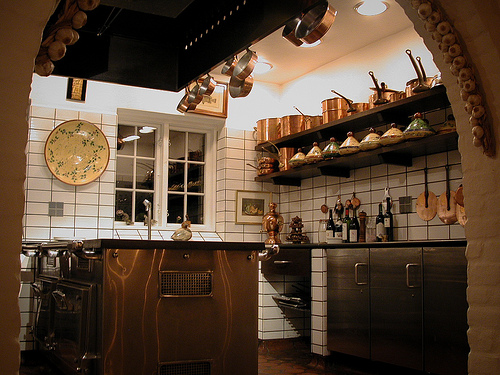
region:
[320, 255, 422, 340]
silver handles on cupboards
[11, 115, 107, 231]
decorative plate hanging on wall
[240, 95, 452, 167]
cooking pots and serving bowls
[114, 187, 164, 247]
a tall silver sink faucet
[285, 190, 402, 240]
bottles of wine on the counter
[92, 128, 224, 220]
a window with reflection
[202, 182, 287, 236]
a oicture hanging on wall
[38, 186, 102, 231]
white and gray tile back splash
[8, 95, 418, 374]
a decorative kitchen area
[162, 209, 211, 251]
a knick knack on counter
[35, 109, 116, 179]
bowl hanging on the wall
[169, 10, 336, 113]
eight pans hanging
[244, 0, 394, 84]
three lights in the ceiling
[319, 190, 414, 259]
bottles on the counter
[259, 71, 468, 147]
pots on the top shelf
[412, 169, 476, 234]
boards hanging on the wal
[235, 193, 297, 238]
picture on the wall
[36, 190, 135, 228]
white tiles on the wall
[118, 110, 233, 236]
two windows in the building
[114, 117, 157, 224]
six panes in one window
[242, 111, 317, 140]
copper pots on top of a shelf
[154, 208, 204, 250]
quail statue on a table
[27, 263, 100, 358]
big metal ovens in kitchen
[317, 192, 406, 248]
bottles of wine on top of table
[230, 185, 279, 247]
picture hanging on a wall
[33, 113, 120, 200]
decorative bowl on the wall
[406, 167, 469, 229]
fans on the side of the wall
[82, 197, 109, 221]
white tiles on the wall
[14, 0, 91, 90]
garlic hanging above stoves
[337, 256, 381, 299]
metal handles on cupboards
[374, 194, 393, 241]
Two different bottles of wine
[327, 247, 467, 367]
Stainless steel cabinet doors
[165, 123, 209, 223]
White framed rectangular window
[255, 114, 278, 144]
Copper coated cooking pot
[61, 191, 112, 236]
White wall tiles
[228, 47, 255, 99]
Copper coated cooking pans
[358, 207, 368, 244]
Pepper grinder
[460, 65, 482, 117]
Bundle of garlic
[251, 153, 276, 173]
A stack of copper coated frying pans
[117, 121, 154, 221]
Window with a reflection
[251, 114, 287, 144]
Copper pot sitting on kitchen shelf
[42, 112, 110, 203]
Decorative bowl hanging on kitchen wall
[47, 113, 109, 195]
Decorative bowl is yellow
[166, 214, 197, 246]
Ceramic duck sitting on kitchen sink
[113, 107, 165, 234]
Kitchen window is closed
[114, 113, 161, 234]
Kitchen window has 6 panes of glass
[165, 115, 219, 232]
Kitchen window is closed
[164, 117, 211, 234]
Kitchen window has 6 panes of glass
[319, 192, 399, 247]
Kitchen counter has many bottles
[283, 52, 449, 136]
Copper cooking pot lined up on shelf